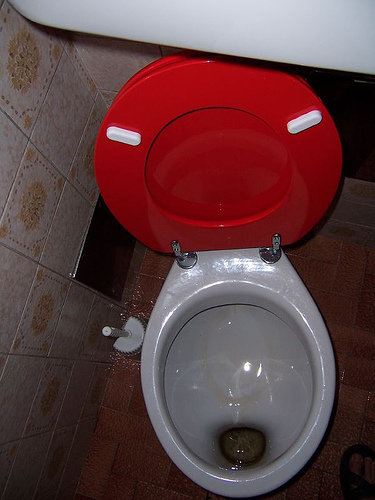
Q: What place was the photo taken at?
A: It was taken at the restroom.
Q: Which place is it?
A: It is a restroom.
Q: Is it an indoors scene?
A: Yes, it is indoors.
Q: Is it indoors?
A: Yes, it is indoors.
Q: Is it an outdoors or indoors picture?
A: It is indoors.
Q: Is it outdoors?
A: No, it is indoors.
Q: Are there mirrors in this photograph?
A: No, there are no mirrors.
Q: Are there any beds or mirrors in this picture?
A: No, there are no mirrors or beds.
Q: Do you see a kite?
A: No, there are no kites.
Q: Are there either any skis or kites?
A: No, there are no kites or skis.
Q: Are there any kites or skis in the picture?
A: No, there are no kites or skis.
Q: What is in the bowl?
A: The water is in the bowl.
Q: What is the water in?
A: The water is in the bowl.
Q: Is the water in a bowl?
A: Yes, the water is in a bowl.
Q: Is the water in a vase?
A: No, the water is in a bowl.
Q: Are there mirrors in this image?
A: No, there are no mirrors.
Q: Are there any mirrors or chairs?
A: No, there are no mirrors or chairs.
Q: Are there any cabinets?
A: No, there are no cabinets.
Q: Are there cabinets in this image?
A: No, there are no cabinets.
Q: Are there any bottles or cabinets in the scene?
A: No, there are no cabinets or bottles.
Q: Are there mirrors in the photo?
A: No, there are no mirrors.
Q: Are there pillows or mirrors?
A: No, there are no mirrors or pillows.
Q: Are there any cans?
A: No, there are no cans.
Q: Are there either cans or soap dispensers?
A: No, there are no cans or soap dispensers.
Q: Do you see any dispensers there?
A: No, there are no dispensers.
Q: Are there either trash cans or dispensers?
A: No, there are no dispensers or trash cans.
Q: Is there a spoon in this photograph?
A: No, there are no spoons.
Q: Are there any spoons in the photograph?
A: No, there are no spoons.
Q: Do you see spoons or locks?
A: No, there are no spoons or locks.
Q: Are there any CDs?
A: No, there are no cds.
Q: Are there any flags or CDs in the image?
A: No, there are no CDs or flags.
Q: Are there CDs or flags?
A: No, there are no CDs or flags.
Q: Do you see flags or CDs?
A: No, there are no CDs or flags.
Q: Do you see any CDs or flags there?
A: No, there are no CDs or flags.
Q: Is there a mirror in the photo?
A: No, there are no mirrors.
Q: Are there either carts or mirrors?
A: No, there are no mirrors or carts.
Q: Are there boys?
A: No, there are no boys.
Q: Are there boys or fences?
A: No, there are no boys or fences.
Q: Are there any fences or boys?
A: No, there are no boys or fences.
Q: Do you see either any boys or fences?
A: No, there are no boys or fences.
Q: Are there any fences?
A: No, there are no fences.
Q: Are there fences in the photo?
A: No, there are no fences.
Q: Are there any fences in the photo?
A: No, there are no fences.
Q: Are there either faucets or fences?
A: No, there are no fences or faucets.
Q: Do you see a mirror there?
A: No, there are no mirrors.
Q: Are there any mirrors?
A: No, there are no mirrors.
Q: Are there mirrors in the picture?
A: No, there are no mirrors.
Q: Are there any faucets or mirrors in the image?
A: No, there are no mirrors or faucets.